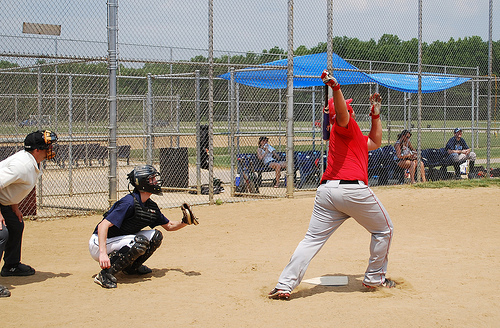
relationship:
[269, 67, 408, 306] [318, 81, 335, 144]
man using bat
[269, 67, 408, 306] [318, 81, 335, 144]
man has bat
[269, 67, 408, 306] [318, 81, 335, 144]
man with bat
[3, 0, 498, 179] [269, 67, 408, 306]
fence beside man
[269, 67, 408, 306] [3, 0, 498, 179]
man beside fence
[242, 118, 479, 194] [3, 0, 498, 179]
people behind fence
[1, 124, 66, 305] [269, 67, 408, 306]
umpire behind man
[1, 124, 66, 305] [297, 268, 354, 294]
umpire above plate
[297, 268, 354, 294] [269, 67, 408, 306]
plate below man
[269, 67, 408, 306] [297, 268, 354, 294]
man above plate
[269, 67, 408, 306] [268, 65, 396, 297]
man with body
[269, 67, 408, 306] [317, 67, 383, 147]
man with arms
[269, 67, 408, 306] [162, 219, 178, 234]
man with elbow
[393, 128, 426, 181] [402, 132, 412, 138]
woman with sunglasses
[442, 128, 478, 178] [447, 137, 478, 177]
man in uniform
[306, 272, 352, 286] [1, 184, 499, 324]
home base placed on ground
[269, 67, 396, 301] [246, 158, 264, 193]
batter lost bat